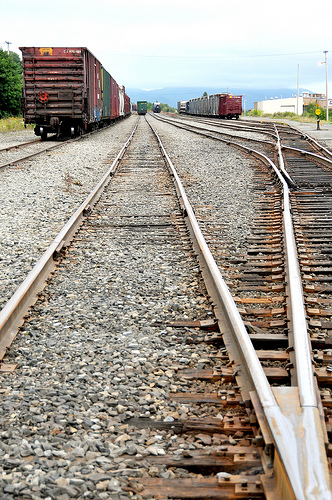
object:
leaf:
[9, 92, 12, 96]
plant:
[0, 51, 22, 117]